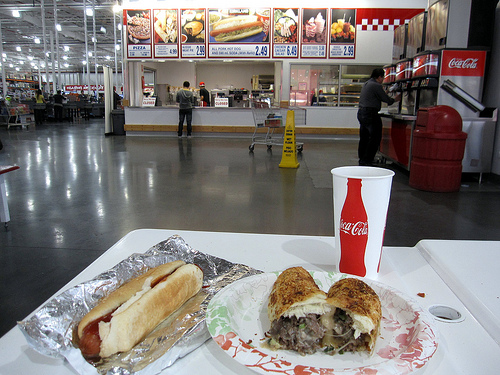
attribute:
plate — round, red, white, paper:
[205, 263, 439, 369]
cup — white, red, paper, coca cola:
[329, 164, 395, 272]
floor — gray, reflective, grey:
[4, 118, 500, 324]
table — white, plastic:
[2, 225, 499, 372]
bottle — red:
[338, 181, 371, 281]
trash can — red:
[404, 103, 475, 193]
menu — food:
[116, 5, 358, 62]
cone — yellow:
[277, 108, 304, 171]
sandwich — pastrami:
[268, 263, 389, 357]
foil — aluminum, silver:
[21, 231, 277, 368]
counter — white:
[126, 92, 271, 111]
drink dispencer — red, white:
[372, 39, 493, 167]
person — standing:
[175, 77, 206, 137]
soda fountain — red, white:
[375, 44, 490, 174]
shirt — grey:
[170, 88, 197, 111]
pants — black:
[178, 107, 194, 132]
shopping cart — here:
[246, 87, 314, 155]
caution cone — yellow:
[280, 111, 304, 170]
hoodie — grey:
[175, 87, 197, 112]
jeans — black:
[178, 114, 194, 135]